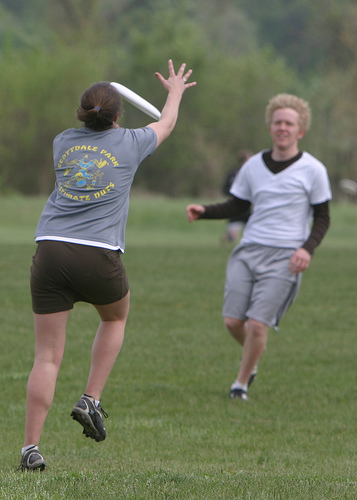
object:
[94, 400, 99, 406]
sock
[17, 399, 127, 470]
sneakers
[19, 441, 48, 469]
shoes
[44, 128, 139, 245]
shirt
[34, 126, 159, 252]
gray shirt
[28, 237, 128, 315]
brown shorts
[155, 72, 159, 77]
fingernail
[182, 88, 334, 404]
man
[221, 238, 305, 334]
shorts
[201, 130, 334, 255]
shirt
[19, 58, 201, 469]
person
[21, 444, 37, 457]
sock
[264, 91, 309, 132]
hair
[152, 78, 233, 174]
wall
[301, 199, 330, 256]
sleeve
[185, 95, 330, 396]
boy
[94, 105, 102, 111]
band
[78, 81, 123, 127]
hair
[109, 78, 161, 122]
frisbee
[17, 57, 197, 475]
woman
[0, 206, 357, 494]
field